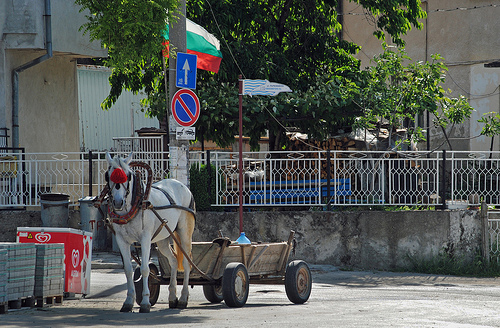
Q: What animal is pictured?
A: A horse.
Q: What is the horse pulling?
A: A wagon.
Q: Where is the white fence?
A: On the cement wall.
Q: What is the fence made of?
A: Metal.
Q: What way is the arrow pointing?
A: Up.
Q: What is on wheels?
A: The wood wagon.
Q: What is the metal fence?
A: White.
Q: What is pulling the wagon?
A: The horse.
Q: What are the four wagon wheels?
A: Black.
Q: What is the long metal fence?
A: White.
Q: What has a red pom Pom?
A: Small white horse.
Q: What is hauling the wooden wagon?
A: The small white horse.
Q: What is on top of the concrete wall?
A: Long white metal fence.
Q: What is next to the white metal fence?
A: The flagged street sign.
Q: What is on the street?
A: The white horse.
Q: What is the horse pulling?
A: A cart.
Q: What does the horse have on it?
A: A harness.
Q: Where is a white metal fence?
A: On top of concrete wall.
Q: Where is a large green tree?
A: Behind the fence.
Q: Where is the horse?
A: To the left.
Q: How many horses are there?
A: 1.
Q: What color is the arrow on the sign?
A: White.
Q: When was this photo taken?
A: During the day.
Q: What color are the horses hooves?
A: Black.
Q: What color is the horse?
A: Off White.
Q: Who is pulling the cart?
A: The horse.